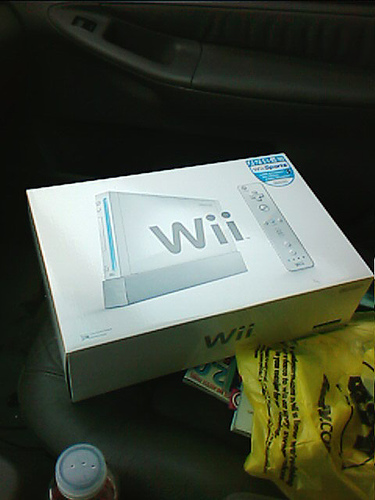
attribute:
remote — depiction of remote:
[237, 178, 314, 274]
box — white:
[21, 150, 372, 406]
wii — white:
[23, 143, 374, 374]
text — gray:
[152, 185, 248, 266]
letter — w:
[146, 214, 211, 255]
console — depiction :
[94, 189, 249, 311]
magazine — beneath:
[181, 350, 237, 399]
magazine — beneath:
[229, 380, 252, 435]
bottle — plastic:
[47, 443, 117, 499]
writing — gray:
[157, 209, 262, 247]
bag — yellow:
[242, 333, 362, 489]